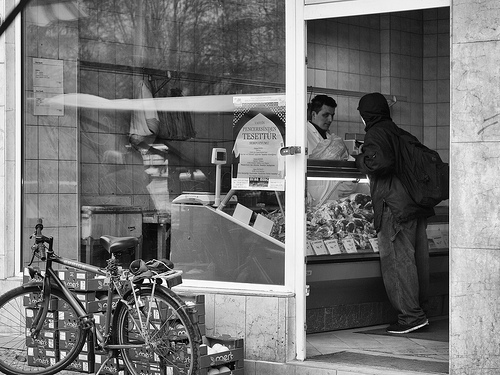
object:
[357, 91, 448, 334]
man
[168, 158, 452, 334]
counter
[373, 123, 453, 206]
backpack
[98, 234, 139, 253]
seat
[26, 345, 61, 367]
crate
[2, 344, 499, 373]
ground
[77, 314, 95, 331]
pedal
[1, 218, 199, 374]
bike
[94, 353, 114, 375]
kickstand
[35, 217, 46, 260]
handle bar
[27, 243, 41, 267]
brake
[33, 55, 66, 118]
paper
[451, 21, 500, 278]
wall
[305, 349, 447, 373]
rug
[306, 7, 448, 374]
doorway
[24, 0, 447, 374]
store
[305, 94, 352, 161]
man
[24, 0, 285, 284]
window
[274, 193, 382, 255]
food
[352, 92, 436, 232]
hoodie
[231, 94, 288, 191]
sign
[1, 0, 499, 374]
photo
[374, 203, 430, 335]
jeans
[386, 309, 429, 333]
shoe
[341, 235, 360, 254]
sign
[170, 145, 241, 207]
scale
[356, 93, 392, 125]
head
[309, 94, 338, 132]
head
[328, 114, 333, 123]
nose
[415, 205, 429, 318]
leg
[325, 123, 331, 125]
mouth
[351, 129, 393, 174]
arm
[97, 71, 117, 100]
tile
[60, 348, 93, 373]
crate